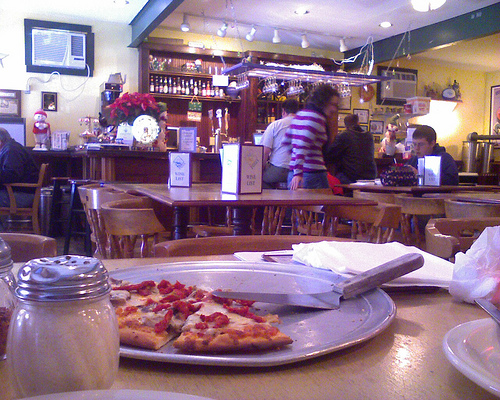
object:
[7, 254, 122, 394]
shaker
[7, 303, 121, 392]
grated cheese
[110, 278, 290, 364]
pizza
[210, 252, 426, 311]
spatula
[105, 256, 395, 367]
pizza pan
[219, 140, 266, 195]
menu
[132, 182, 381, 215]
table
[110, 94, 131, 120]
flowers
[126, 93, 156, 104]
poinsettias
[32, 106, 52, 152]
snowman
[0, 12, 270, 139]
background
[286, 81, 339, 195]
woman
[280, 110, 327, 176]
striped shirt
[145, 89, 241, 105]
shelf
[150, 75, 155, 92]
liquor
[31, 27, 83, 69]
air conditioning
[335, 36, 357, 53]
spotlights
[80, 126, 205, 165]
bar counter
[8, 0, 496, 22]
ceiling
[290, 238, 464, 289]
napkins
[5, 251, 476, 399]
brown table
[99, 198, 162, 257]
chair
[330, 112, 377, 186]
man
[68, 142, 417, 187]
bar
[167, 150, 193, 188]
menus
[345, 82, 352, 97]
wine glasses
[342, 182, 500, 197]
tables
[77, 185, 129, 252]
chairs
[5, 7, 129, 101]
wall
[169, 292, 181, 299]
red pepperonis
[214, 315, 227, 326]
red pepperoni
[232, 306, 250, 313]
red pepperoni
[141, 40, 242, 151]
shelves